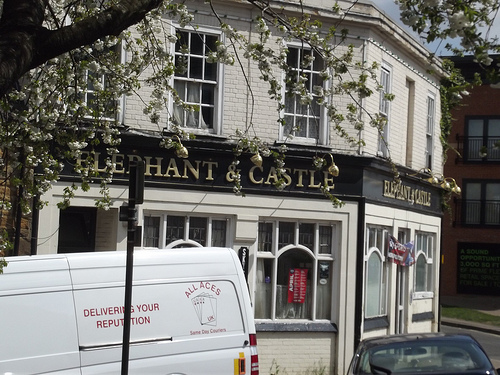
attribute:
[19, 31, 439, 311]
building — white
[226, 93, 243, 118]
brick — white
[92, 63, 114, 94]
blossoms — white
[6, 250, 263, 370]
van — white, delivering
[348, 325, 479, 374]
car — black, dark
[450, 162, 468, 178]
brick — red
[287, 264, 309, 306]
dates — red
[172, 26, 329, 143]
windows — open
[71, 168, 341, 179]
lettering — gold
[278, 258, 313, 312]
sign — red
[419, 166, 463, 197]
lights — gold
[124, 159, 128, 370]
pole — black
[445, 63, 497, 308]
building — behind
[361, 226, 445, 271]
banner — flag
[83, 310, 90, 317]
d — red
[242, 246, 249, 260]
letters — white